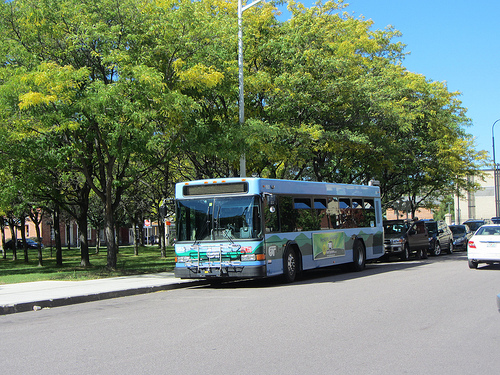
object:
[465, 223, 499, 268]
vehicle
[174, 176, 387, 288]
bus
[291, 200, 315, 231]
passenger window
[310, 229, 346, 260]
advertisement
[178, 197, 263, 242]
windshield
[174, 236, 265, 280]
bumper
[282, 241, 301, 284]
left front wheel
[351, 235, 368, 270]
left back wheel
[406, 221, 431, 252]
door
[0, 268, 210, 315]
sidewalk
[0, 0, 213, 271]
tree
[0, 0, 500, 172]
sky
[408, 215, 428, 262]
person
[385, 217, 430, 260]
car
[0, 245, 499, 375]
road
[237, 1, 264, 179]
light post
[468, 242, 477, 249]
tail light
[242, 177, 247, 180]
circle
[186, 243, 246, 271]
bike rack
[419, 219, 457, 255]
car